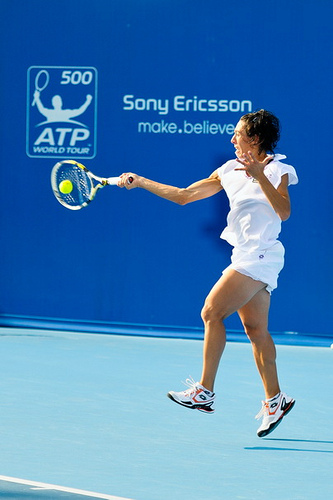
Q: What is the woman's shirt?
A: White.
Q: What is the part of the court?
A: Tennis.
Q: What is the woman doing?
A: Jumping.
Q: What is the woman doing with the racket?
A: Swinging.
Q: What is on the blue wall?
A: White writing.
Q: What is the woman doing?
A: Playing tennis.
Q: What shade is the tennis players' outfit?
A: White.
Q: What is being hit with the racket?
A: Ball.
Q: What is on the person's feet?
A: Sneakers.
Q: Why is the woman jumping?
A: Playing tennis.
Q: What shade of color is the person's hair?
A: Black.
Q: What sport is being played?
A: Tennis.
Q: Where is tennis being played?
A: Tennis court.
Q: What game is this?
A: Tennis.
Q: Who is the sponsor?
A: Sony Ericsson.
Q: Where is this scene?
A: A tennis court.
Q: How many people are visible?
A: One.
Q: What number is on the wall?
A: 500.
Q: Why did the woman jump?
A: To hit the ball better.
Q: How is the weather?
A: Sunny.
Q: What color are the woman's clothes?
A: White.